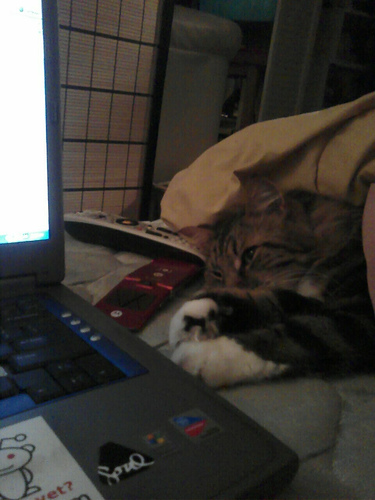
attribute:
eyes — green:
[197, 231, 276, 285]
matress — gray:
[65, 220, 356, 456]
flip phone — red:
[97, 254, 204, 346]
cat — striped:
[164, 176, 374, 389]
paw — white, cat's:
[172, 331, 290, 387]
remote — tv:
[63, 206, 212, 266]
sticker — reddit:
[1, 413, 106, 496]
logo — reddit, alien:
[7, 441, 63, 495]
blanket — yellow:
[160, 91, 374, 246]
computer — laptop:
[1, 0, 298, 499]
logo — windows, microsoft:
[68, 256, 222, 439]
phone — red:
[101, 255, 196, 331]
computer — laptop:
[1, 254, 280, 485]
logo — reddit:
[5, 411, 75, 497]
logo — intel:
[181, 407, 223, 448]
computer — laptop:
[1, 265, 202, 498]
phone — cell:
[97, 249, 208, 328]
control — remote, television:
[85, 190, 197, 269]